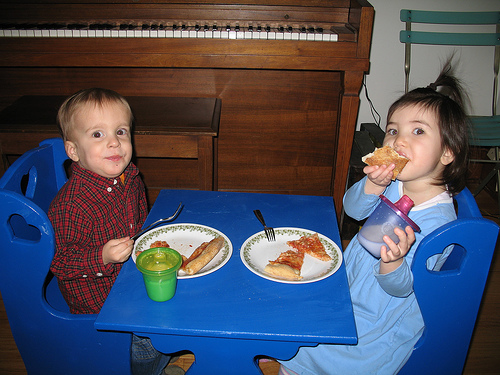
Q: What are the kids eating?
A: Food.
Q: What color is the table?
A: Blue.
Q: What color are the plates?
A: White.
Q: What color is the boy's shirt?
A: Red.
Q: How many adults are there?
A: None.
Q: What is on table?
A: Plate with pizza and fork.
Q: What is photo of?
A: 2 toddlers eating pizza.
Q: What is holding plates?
A: Blue table.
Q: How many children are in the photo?
A: Two.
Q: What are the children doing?
A: Eating.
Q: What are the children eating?
A: Pizza.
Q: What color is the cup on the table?
A: Green.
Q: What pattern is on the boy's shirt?
A: Plaid.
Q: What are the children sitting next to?
A: Piano.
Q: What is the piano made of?
A: Wood.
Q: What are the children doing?
A: Eating.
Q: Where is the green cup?
A: On a table.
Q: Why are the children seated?
A: It's time to eat.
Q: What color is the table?
A: Blue.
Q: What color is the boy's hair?
A: Blonde.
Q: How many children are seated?
A: Two.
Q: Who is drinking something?
A: A girl.